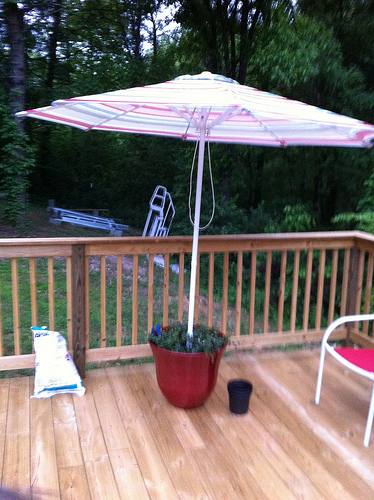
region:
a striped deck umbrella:
[31, 52, 366, 169]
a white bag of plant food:
[28, 320, 91, 409]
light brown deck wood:
[92, 409, 201, 492]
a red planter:
[145, 316, 222, 409]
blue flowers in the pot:
[150, 324, 205, 350]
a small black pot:
[220, 376, 263, 426]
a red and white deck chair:
[309, 292, 370, 450]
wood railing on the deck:
[229, 234, 327, 323]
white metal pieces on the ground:
[48, 184, 184, 242]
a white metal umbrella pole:
[185, 124, 210, 343]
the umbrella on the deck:
[4, 71, 372, 497]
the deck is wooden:
[1, 228, 372, 498]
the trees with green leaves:
[186, 1, 373, 239]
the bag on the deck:
[29, 321, 96, 403]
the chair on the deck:
[312, 303, 373, 460]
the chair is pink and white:
[314, 311, 373, 450]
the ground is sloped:
[14, 208, 216, 316]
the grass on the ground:
[17, 213, 122, 315]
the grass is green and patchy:
[8, 230, 171, 309]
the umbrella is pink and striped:
[14, 57, 373, 331]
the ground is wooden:
[75, 411, 306, 499]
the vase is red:
[150, 348, 218, 413]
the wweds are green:
[163, 324, 218, 349]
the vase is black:
[225, 376, 256, 416]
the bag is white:
[29, 331, 82, 395]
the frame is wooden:
[75, 233, 186, 327]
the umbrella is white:
[101, 78, 336, 147]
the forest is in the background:
[127, 156, 370, 210]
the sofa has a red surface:
[335, 344, 369, 372]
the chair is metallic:
[311, 328, 371, 438]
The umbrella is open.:
[4, 47, 371, 340]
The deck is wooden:
[0, 216, 371, 494]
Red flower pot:
[135, 316, 232, 417]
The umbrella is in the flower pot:
[30, 56, 371, 381]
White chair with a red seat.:
[309, 307, 372, 443]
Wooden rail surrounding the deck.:
[6, 227, 373, 332]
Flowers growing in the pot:
[129, 309, 235, 359]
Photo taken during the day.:
[2, 0, 363, 110]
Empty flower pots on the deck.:
[219, 370, 269, 425]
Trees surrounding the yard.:
[4, 68, 369, 319]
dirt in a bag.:
[28, 324, 87, 398]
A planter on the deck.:
[224, 374, 258, 416]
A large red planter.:
[143, 317, 228, 413]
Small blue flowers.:
[147, 319, 163, 338]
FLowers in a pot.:
[142, 314, 230, 415]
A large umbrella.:
[2, 37, 373, 180]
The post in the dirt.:
[185, 117, 210, 347]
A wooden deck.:
[103, 422, 315, 496]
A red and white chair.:
[310, 281, 373, 446]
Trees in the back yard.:
[4, 0, 369, 228]